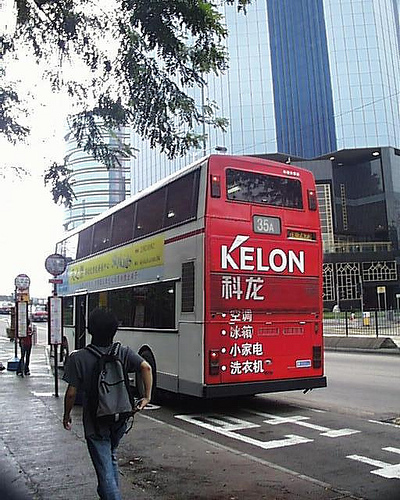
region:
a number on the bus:
[255, 218, 272, 232]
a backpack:
[89, 353, 134, 417]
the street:
[346, 361, 389, 399]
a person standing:
[20, 339, 33, 373]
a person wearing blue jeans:
[88, 440, 124, 499]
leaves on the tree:
[40, 163, 80, 209]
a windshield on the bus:
[226, 169, 306, 205]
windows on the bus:
[98, 216, 162, 236]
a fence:
[345, 308, 385, 333]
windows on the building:
[236, 124, 279, 150]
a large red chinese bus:
[50, 182, 362, 423]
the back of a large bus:
[203, 147, 325, 393]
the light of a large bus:
[202, 341, 234, 385]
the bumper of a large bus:
[208, 364, 333, 406]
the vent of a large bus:
[162, 261, 211, 315]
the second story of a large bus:
[57, 228, 226, 278]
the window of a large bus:
[126, 286, 178, 343]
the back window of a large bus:
[220, 156, 300, 209]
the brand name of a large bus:
[211, 236, 301, 274]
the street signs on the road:
[209, 409, 364, 492]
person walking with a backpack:
[49, 304, 163, 498]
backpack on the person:
[81, 350, 135, 428]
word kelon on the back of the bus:
[214, 235, 310, 276]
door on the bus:
[70, 295, 89, 348]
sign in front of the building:
[372, 283, 390, 314]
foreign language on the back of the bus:
[224, 311, 269, 379]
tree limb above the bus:
[43, 180, 81, 212]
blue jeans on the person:
[90, 439, 126, 499]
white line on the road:
[248, 450, 274, 471]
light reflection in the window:
[164, 209, 178, 222]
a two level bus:
[53, 181, 323, 393]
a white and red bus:
[40, 164, 314, 381]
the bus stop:
[11, 251, 121, 385]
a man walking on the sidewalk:
[68, 329, 154, 470]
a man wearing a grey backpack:
[61, 329, 169, 496]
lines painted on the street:
[216, 395, 393, 485]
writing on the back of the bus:
[214, 250, 303, 369]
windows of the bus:
[64, 281, 185, 338]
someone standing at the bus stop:
[11, 312, 41, 372]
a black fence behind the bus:
[328, 307, 384, 331]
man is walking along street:
[54, 299, 162, 498]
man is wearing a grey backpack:
[55, 304, 156, 499]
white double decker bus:
[45, 133, 331, 407]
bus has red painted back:
[195, 149, 332, 403]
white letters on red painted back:
[201, 149, 331, 394]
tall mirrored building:
[123, 104, 388, 314]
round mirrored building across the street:
[53, 105, 130, 230]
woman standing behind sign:
[17, 309, 37, 381]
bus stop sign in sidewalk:
[44, 253, 71, 401]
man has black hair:
[66, 306, 151, 498]